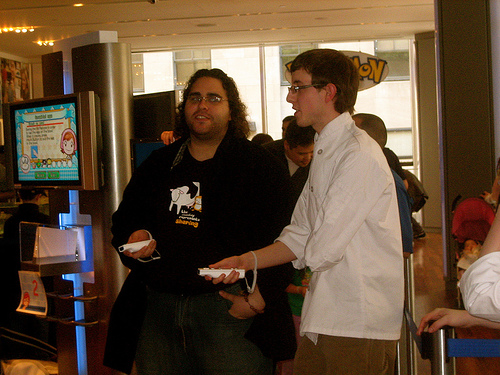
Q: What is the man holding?
A: Wii remote.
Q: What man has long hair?
A: Left man.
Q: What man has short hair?
A: Right man.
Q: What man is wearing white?
A: Right man.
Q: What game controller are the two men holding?
A: Wii motes.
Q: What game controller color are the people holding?
A: White.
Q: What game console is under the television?
A: Wii.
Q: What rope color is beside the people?
A: Blue.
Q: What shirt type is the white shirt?
A: Button up.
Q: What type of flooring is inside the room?
A: Hardwood.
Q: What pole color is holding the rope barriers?
A: Silver.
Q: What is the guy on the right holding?
A: A Wii remote.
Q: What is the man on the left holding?
A: A Wii remote.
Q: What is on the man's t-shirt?
A: A design.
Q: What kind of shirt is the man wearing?
A: A chef shirt.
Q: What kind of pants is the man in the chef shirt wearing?
A: Khakis.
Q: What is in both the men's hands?
A: Wii remotes.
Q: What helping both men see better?
A: Glasses.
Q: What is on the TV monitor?
A: Video game.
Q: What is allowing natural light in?
A: The window.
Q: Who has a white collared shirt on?
A: Man on the right.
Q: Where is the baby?
A: In the stroller.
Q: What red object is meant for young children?
A: The stroller.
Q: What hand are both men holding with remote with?
A: Right hand.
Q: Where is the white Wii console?
A: Below the TV.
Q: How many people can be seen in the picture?
A: 5.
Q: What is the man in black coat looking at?
A: The camera.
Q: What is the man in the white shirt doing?
A: Playing WII.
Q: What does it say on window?
A: Pokemon.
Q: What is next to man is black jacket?
A: A monitor.